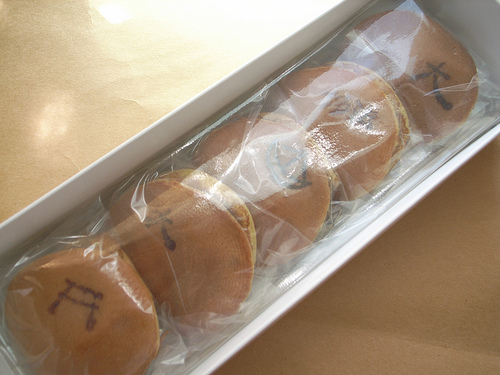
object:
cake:
[354, 5, 481, 147]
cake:
[0, 238, 178, 368]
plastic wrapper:
[0, 220, 191, 374]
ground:
[209, 131, 498, 375]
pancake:
[3, 3, 488, 374]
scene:
[1, 35, 498, 373]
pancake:
[335, 8, 478, 144]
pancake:
[265, 58, 412, 199]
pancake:
[191, 111, 333, 267]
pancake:
[107, 167, 257, 324]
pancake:
[2, 234, 159, 373]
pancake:
[330, 7, 490, 140]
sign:
[416, 60, 456, 110]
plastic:
[1, 194, 188, 373]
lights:
[128, 175, 153, 225]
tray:
[2, 0, 496, 373]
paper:
[0, 5, 305, 192]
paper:
[255, 141, 494, 371]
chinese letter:
[327, 93, 379, 136]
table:
[0, 0, 500, 375]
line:
[122, 98, 141, 102]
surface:
[2, 0, 497, 374]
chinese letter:
[47, 277, 105, 332]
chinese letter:
[142, 206, 177, 253]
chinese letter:
[264, 142, 312, 190]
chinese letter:
[415, 61, 452, 111]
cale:
[347, 7, 477, 143]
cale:
[274, 61, 414, 208]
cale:
[196, 120, 341, 255]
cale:
[121, 167, 254, 334]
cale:
[6, 234, 163, 374]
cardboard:
[2, 2, 498, 374]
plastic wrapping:
[321, 46, 421, 153]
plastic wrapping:
[290, 9, 451, 209]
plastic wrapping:
[178, 98, 362, 349]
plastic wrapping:
[47, 182, 330, 368]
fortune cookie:
[203, 112, 345, 236]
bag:
[3, 187, 196, 373]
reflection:
[85, 1, 334, 112]